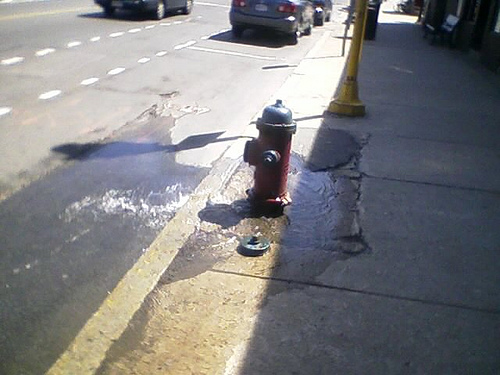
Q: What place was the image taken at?
A: It was taken at the road.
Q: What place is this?
A: It is a road.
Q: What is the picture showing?
A: It is showing a road.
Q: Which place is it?
A: It is a road.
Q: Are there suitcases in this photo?
A: No, there are no suitcases.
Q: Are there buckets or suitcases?
A: No, there are no suitcases or buckets.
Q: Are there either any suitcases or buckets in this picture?
A: No, there are no suitcases or buckets.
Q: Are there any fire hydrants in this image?
A: Yes, there is a fire hydrant.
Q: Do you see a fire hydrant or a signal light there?
A: Yes, there is a fire hydrant.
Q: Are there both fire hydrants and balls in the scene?
A: No, there is a fire hydrant but no balls.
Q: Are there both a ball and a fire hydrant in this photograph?
A: No, there is a fire hydrant but no balls.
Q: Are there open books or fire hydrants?
A: Yes, there is an open fire hydrant.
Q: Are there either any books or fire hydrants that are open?
A: Yes, the fire hydrant is open.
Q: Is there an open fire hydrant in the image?
A: Yes, there is an open fire hydrant.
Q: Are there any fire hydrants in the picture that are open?
A: Yes, there is a fire hydrant that is open.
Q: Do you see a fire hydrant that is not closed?
A: Yes, there is a open fire hydrant.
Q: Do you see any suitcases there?
A: No, there are no suitcases.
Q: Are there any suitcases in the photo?
A: No, there are no suitcases.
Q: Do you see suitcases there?
A: No, there are no suitcases.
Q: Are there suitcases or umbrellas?
A: No, there are no suitcases or umbrellas.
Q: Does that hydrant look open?
A: Yes, the hydrant is open.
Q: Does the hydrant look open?
A: Yes, the hydrant is open.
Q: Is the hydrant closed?
A: No, the hydrant is open.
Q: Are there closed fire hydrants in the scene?
A: No, there is a fire hydrant but it is open.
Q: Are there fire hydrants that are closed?
A: No, there is a fire hydrant but it is open.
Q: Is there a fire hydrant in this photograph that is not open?
A: No, there is a fire hydrant but it is open.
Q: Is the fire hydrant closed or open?
A: The fire hydrant is open.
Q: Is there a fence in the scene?
A: No, there are no fences.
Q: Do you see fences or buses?
A: No, there are no fences or buses.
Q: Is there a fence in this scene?
A: No, there are no fences.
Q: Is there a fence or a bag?
A: No, there are no fences or bags.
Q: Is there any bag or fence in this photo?
A: No, there are no fences or bags.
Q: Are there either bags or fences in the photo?
A: No, there are no fences or bags.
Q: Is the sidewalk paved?
A: Yes, the sidewalk is paved.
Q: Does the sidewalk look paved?
A: Yes, the sidewalk is paved.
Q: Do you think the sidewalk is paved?
A: Yes, the sidewalk is paved.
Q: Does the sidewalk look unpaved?
A: No, the sidewalk is paved.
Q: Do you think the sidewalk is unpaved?
A: No, the sidewalk is paved.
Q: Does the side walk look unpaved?
A: No, the side walk is paved.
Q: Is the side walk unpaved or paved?
A: The side walk is paved.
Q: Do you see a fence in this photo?
A: No, there are no fences.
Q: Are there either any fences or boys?
A: No, there are no fences or boys.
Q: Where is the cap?
A: The cap is on the side walk.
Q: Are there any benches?
A: Yes, there is a bench.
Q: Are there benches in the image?
A: Yes, there is a bench.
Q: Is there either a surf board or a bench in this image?
A: Yes, there is a bench.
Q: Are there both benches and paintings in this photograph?
A: No, there is a bench but no paintings.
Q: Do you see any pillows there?
A: No, there are no pillows.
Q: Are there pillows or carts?
A: No, there are no pillows or carts.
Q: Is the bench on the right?
A: Yes, the bench is on the right of the image.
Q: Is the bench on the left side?
A: No, the bench is on the right of the image.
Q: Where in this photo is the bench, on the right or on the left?
A: The bench is on the right of the image.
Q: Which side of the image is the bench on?
A: The bench is on the right of the image.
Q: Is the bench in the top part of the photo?
A: Yes, the bench is in the top of the image.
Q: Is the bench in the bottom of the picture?
A: No, the bench is in the top of the image.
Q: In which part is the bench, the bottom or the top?
A: The bench is in the top of the image.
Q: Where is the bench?
A: The bench is on the sidewalk.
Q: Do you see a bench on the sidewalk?
A: Yes, there is a bench on the sidewalk.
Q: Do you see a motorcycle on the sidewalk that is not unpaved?
A: No, there is a bench on the sidewalk.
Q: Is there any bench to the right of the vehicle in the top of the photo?
A: Yes, there is a bench to the right of the car.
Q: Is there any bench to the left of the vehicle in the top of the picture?
A: No, the bench is to the right of the car.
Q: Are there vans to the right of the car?
A: No, there is a bench to the right of the car.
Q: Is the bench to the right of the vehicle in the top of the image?
A: Yes, the bench is to the right of the car.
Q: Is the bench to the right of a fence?
A: No, the bench is to the right of the car.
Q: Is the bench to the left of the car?
A: No, the bench is to the right of the car.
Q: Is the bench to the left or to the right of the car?
A: The bench is to the right of the car.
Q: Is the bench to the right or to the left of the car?
A: The bench is to the right of the car.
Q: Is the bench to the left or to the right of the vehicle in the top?
A: The bench is to the right of the car.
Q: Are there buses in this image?
A: No, there are no buses.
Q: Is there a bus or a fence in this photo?
A: No, there are no buses or fences.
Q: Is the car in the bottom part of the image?
A: No, the car is in the top of the image.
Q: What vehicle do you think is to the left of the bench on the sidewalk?
A: The vehicle is a car.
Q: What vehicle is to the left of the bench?
A: The vehicle is a car.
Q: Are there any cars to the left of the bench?
A: Yes, there is a car to the left of the bench.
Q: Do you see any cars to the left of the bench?
A: Yes, there is a car to the left of the bench.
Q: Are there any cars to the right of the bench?
A: No, the car is to the left of the bench.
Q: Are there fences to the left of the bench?
A: No, there is a car to the left of the bench.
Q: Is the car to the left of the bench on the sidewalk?
A: Yes, the car is to the left of the bench.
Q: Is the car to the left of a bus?
A: No, the car is to the left of the bench.